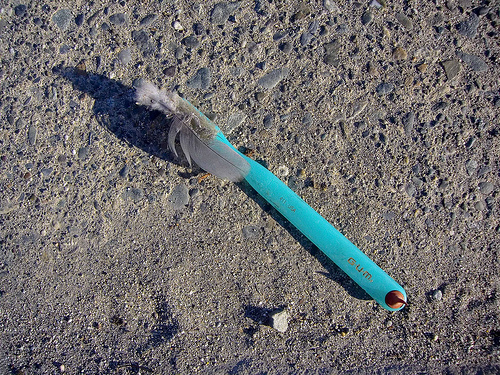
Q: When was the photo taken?
A: Daytime.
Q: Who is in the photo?
A: Nobody.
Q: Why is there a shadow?
A: It is sunny.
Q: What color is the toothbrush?
A: Blue.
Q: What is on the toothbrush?
A: A feather.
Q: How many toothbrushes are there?
A: One.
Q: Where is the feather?
A: On the toothbrush.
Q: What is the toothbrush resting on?
A: The ground.